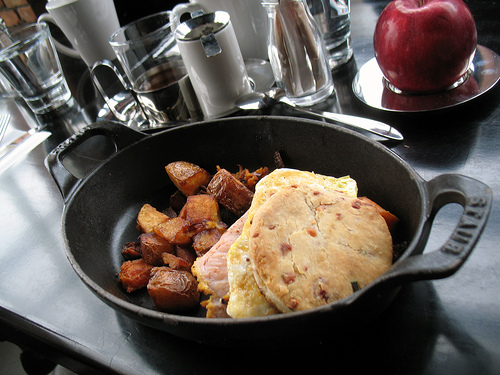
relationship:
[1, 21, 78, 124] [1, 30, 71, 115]
glass containing water